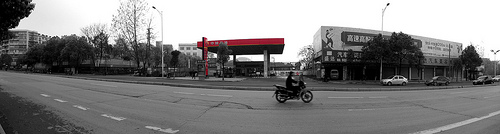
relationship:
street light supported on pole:
[151, 2, 162, 12] [161, 18, 167, 78]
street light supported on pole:
[386, 2, 393, 12] [381, 15, 382, 82]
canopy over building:
[199, 38, 288, 51] [234, 56, 270, 75]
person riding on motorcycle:
[288, 71, 297, 90] [276, 87, 313, 102]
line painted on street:
[39, 88, 56, 99] [39, 73, 496, 127]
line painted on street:
[102, 109, 131, 125] [39, 73, 496, 127]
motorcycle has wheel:
[276, 87, 313, 102] [273, 94, 290, 102]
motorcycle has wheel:
[276, 87, 313, 102] [299, 92, 315, 101]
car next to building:
[383, 74, 414, 89] [317, 28, 481, 77]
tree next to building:
[216, 36, 234, 76] [234, 56, 270, 75]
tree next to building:
[58, 36, 94, 72] [0, 30, 43, 57]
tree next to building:
[37, 38, 56, 71] [0, 30, 43, 57]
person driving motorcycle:
[288, 71, 297, 90] [276, 87, 313, 102]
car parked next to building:
[427, 74, 447, 85] [317, 28, 481, 77]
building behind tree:
[0, 30, 43, 57] [37, 38, 56, 71]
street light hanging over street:
[151, 2, 162, 12] [39, 73, 496, 127]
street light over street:
[386, 2, 393, 12] [39, 73, 496, 127]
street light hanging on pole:
[151, 2, 162, 12] [161, 18, 167, 78]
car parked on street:
[472, 73, 498, 87] [39, 73, 496, 127]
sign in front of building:
[204, 38, 210, 76] [234, 56, 270, 75]